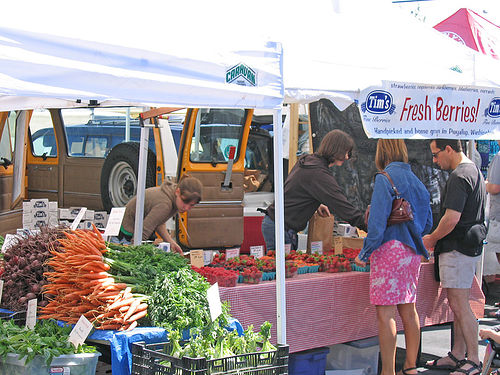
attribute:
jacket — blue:
[361, 162, 435, 262]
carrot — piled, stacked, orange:
[80, 264, 108, 274]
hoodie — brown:
[122, 174, 178, 241]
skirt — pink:
[366, 239, 426, 306]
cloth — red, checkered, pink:
[202, 259, 486, 354]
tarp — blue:
[0, 306, 246, 373]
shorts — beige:
[434, 246, 483, 289]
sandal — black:
[426, 352, 466, 367]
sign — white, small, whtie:
[355, 86, 499, 140]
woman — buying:
[354, 140, 432, 375]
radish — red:
[29, 280, 43, 296]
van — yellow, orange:
[1, 106, 254, 256]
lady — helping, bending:
[262, 126, 367, 255]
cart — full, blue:
[131, 338, 290, 374]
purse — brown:
[375, 167, 414, 225]